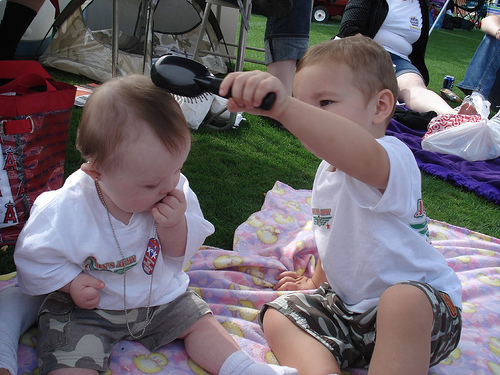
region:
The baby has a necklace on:
[26, 112, 232, 374]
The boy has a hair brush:
[112, 32, 372, 174]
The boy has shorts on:
[249, 247, 495, 357]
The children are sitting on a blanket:
[11, 190, 454, 353]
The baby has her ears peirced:
[63, 147, 128, 192]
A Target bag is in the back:
[426, 96, 481, 145]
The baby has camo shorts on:
[18, 262, 205, 372]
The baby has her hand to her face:
[126, 171, 205, 250]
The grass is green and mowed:
[208, 127, 291, 214]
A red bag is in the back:
[6, 86, 96, 211]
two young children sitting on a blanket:
[22, 23, 474, 369]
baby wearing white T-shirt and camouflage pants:
[7, 72, 274, 373]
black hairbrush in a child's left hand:
[146, 49, 288, 120]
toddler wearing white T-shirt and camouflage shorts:
[251, 18, 472, 369]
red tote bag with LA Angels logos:
[0, 53, 85, 257]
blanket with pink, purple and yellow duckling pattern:
[191, 243, 294, 326]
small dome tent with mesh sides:
[44, 1, 246, 96]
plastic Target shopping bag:
[423, 94, 495, 155]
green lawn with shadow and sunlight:
[199, 127, 309, 198]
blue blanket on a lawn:
[425, 153, 498, 228]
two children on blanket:
[48, 29, 463, 374]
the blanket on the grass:
[0, 167, 499, 373]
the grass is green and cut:
[198, 137, 279, 182]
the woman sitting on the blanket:
[331, 0, 479, 130]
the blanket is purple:
[380, 109, 499, 183]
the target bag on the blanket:
[413, 104, 497, 166]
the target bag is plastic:
[423, 97, 498, 145]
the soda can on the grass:
[445, 69, 460, 93]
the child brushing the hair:
[18, 15, 469, 374]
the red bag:
[1, 55, 72, 262]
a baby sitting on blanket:
[28, 76, 291, 373]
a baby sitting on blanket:
[220, 37, 464, 373]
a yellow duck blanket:
[2, 181, 496, 373]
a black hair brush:
[145, 49, 273, 119]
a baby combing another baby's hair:
[15, 22, 468, 373]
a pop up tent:
[39, 6, 231, 96]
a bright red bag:
[0, 56, 85, 244]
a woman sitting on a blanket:
[335, 0, 475, 128]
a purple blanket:
[382, 110, 497, 217]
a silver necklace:
[88, 170, 160, 347]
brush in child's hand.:
[169, 60, 211, 87]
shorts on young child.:
[50, 324, 103, 356]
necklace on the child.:
[112, 234, 131, 305]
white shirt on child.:
[332, 217, 399, 268]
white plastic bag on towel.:
[454, 123, 486, 147]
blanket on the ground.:
[465, 245, 485, 277]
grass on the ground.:
[225, 165, 254, 188]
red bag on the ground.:
[37, 110, 66, 163]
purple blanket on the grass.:
[468, 166, 498, 186]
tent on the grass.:
[75, 24, 112, 74]